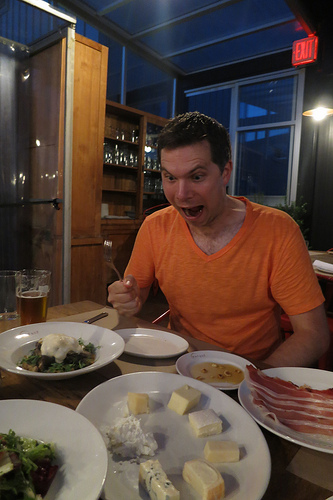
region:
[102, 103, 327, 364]
a man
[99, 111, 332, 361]
a man holding a fork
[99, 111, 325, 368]
a man in an orange shirt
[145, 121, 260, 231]
the man has his mouth open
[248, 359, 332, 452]
uncooked bacon on a plate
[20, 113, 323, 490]
the man looks at a table of food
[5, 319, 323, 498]
white plates are on the table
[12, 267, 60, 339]
a partially filled glass of beer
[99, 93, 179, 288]
a wood cabinet with glasses on the shelves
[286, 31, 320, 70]
a glowing red exit sign hangs by the ceiling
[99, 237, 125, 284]
the fork the man is holding onto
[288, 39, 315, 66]
the exit sign attached to the wall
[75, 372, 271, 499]
a plate full of assorted cheeses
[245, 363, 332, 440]
slices of bacon on another plates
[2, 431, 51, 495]
some salad sitting in a bowl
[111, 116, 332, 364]
a man sitting next to the table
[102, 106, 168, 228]
some shelves filled with assorted glasses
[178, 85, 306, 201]
a window in front of the building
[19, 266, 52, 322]
a glass of beer on the tabl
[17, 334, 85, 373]
a salad with dressing on it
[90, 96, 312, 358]
man in orange shirt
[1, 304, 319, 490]
six white plates with food on them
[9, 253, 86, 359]
glass of beer on brown table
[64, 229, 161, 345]
man holding fork in hand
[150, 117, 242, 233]
man with mouth open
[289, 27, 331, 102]
red exit sign behind man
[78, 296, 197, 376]
one empty white plate on brown table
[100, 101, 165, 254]
shelf with glass ware on it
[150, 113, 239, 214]
man has brown hari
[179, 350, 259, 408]
white plate with brown sauce on it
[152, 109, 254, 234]
man with open mouth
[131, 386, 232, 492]
assorted cheese on plate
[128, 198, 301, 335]
orange tee shirt on man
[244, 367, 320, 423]
raw meat on plate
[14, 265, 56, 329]
glass of beer on table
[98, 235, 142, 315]
fork in clenched fist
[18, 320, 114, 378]
bowl of salad with white dressing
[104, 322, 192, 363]
empty plate on table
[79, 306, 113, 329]
handle of utensil on table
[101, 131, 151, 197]
glasses on cabinet shelves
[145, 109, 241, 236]
head of a person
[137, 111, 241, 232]
head of a man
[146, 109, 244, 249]
man with dark hair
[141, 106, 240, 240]
man with short dark hair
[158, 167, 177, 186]
right eye of a person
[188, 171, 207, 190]
left eye of a person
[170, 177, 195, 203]
nose of a person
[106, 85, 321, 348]
person wearing an orange shirt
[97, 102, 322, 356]
man wearing an orange shirt